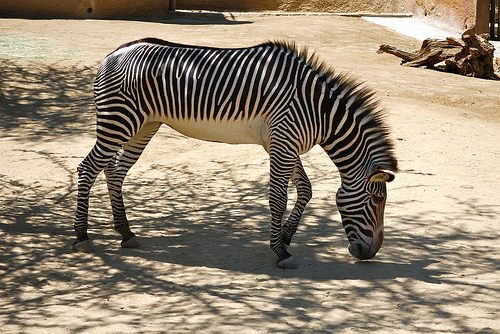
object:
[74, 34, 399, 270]
zebra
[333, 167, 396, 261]
head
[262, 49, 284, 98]
stripe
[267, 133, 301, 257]
leg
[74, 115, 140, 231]
leg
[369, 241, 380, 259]
nose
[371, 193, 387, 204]
eye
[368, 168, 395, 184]
ear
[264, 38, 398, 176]
mane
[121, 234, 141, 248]
hoof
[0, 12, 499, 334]
field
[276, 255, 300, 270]
hoof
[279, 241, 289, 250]
hoof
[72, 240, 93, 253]
hoof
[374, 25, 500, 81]
wood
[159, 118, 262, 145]
belly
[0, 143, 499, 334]
shadow